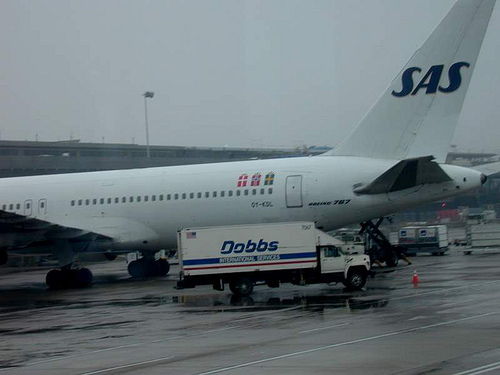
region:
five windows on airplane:
[68, 197, 105, 207]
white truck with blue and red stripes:
[175, 220, 372, 300]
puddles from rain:
[75, 294, 421, 325]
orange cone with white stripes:
[408, 266, 424, 288]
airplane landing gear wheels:
[38, 264, 98, 293]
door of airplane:
[279, 172, 312, 217]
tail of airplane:
[324, 1, 493, 216]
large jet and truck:
[4, 50, 486, 307]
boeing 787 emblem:
[305, 196, 353, 211]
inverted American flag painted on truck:
[184, 229, 201, 241]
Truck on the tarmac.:
[157, 205, 487, 301]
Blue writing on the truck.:
[217, 227, 296, 274]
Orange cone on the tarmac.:
[387, 254, 444, 310]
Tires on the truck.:
[294, 265, 398, 297]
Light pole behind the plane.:
[136, 62, 226, 199]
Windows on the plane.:
[55, 190, 315, 210]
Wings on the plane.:
[327, 153, 462, 219]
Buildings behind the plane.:
[23, 89, 218, 244]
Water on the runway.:
[99, 287, 304, 328]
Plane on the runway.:
[68, 38, 484, 342]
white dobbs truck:
[174, 215, 382, 304]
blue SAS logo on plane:
[367, 20, 494, 145]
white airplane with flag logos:
[31, 97, 493, 317]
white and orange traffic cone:
[406, 265, 431, 295]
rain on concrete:
[152, 297, 377, 373]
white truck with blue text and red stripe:
[170, 203, 414, 319]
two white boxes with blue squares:
[387, 213, 498, 265]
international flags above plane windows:
[230, 165, 287, 200]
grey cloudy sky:
[183, 26, 320, 143]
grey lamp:
[138, 84, 183, 180]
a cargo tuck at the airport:
[172, 218, 387, 302]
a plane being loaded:
[8, 137, 496, 279]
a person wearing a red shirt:
[401, 267, 433, 292]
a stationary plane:
[12, 153, 495, 280]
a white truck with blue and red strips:
[172, 217, 397, 314]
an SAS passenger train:
[2, 11, 492, 310]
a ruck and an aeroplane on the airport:
[6, 2, 499, 309]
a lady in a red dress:
[398, 248, 434, 302]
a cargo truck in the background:
[390, 209, 455, 256]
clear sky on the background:
[0, 0, 498, 165]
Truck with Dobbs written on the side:
[168, 214, 376, 301]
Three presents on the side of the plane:
[229, 170, 283, 191]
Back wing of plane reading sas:
[337, 4, 495, 176]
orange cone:
[393, 257, 435, 295]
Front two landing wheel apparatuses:
[34, 240, 172, 306]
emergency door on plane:
[278, 168, 314, 220]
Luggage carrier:
[388, 220, 463, 267]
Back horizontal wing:
[346, 148, 461, 220]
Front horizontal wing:
[2, 197, 136, 281]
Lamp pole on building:
[106, 57, 182, 167]